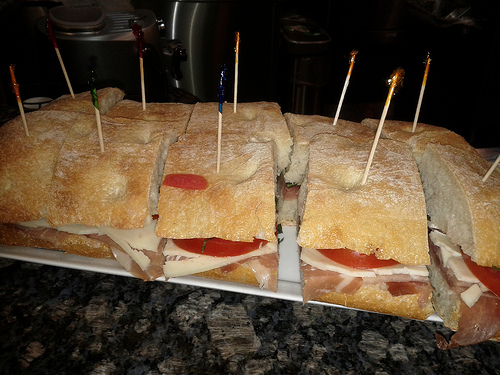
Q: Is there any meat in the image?
A: Yes, there is meat.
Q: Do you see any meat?
A: Yes, there is meat.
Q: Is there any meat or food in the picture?
A: Yes, there is meat.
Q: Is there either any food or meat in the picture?
A: Yes, there is meat.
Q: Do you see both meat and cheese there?
A: Yes, there are both meat and cheese.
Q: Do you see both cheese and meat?
A: Yes, there are both meat and cheese.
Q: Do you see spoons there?
A: No, there are no spoons.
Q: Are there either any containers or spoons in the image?
A: No, there are no spoons or containers.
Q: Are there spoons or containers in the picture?
A: No, there are no spoons or containers.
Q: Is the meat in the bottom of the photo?
A: Yes, the meat is in the bottom of the image.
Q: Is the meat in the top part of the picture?
A: No, the meat is in the bottom of the image.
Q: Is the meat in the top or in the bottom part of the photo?
A: The meat is in the bottom of the image.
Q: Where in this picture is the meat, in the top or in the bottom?
A: The meat is in the bottom of the image.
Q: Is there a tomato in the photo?
A: Yes, there is a tomato.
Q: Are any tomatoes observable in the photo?
A: Yes, there is a tomato.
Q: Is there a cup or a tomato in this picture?
A: Yes, there is a tomato.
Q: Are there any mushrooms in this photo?
A: No, there are no mushrooms.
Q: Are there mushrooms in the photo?
A: No, there are no mushrooms.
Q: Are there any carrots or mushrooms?
A: No, there are no mushrooms or carrots.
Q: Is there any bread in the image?
A: Yes, there is a bread.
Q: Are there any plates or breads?
A: Yes, there is a bread.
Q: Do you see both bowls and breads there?
A: No, there is a bread but no bowls.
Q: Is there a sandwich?
A: Yes, there is a sandwich.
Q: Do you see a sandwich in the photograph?
A: Yes, there is a sandwich.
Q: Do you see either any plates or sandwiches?
A: Yes, there is a sandwich.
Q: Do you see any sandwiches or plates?
A: Yes, there is a sandwich.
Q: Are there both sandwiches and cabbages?
A: No, there is a sandwich but no cabbages.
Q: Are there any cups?
A: No, there are no cups.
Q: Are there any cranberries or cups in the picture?
A: No, there are no cups or cranberries.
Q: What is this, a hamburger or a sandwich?
A: This is a sandwich.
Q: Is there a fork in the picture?
A: No, there are no forks.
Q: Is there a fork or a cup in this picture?
A: No, there are no forks or cups.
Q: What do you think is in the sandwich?
A: The toothpicks are in the sandwich.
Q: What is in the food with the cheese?
A: The toothpicks are in the sandwich.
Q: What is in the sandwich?
A: The toothpicks are in the sandwich.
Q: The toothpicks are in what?
A: The toothpicks are in the sandwich.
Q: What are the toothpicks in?
A: The toothpicks are in the sandwich.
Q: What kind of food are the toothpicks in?
A: The toothpicks are in the sandwich.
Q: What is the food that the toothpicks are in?
A: The food is a sandwich.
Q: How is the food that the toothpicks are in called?
A: The food is a sandwich.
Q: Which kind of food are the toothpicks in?
A: The toothpicks are in the sandwich.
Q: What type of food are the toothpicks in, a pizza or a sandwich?
A: The toothpicks are in a sandwich.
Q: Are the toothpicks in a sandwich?
A: Yes, the toothpicks are in a sandwich.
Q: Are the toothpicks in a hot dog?
A: No, the toothpicks are in a sandwich.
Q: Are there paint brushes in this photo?
A: No, there are no paint brushes.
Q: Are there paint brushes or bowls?
A: No, there are no paint brushes or bowls.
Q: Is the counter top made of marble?
A: Yes, the counter top is made of marble.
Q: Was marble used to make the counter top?
A: Yes, the counter top is made of marble.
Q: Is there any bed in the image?
A: No, there are no beds.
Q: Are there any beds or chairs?
A: No, there are no beds or chairs.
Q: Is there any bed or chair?
A: No, there are no beds or chairs.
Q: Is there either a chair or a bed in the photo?
A: No, there are no beds or chairs.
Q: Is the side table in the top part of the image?
A: Yes, the side table is in the top of the image.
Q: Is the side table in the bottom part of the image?
A: No, the side table is in the top of the image.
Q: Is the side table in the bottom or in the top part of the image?
A: The side table is in the top of the image.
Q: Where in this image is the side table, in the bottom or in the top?
A: The side table is in the top of the image.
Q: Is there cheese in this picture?
A: Yes, there is cheese.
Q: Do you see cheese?
A: Yes, there is cheese.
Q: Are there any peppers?
A: No, there are no peppers.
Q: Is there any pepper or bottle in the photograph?
A: No, there are no peppers or bottles.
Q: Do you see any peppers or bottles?
A: No, there are no peppers or bottles.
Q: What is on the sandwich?
A: The cheese is on the sandwich.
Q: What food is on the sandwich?
A: The food is cheese.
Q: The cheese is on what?
A: The cheese is on the sandwich.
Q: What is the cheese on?
A: The cheese is on the sandwich.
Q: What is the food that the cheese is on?
A: The food is a sandwich.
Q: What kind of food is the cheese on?
A: The cheese is on the sandwich.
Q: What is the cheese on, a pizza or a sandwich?
A: The cheese is on a sandwich.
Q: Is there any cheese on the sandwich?
A: Yes, there is cheese on the sandwich.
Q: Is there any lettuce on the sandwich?
A: No, there is cheese on the sandwich.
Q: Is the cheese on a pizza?
A: No, the cheese is on a sandwich.